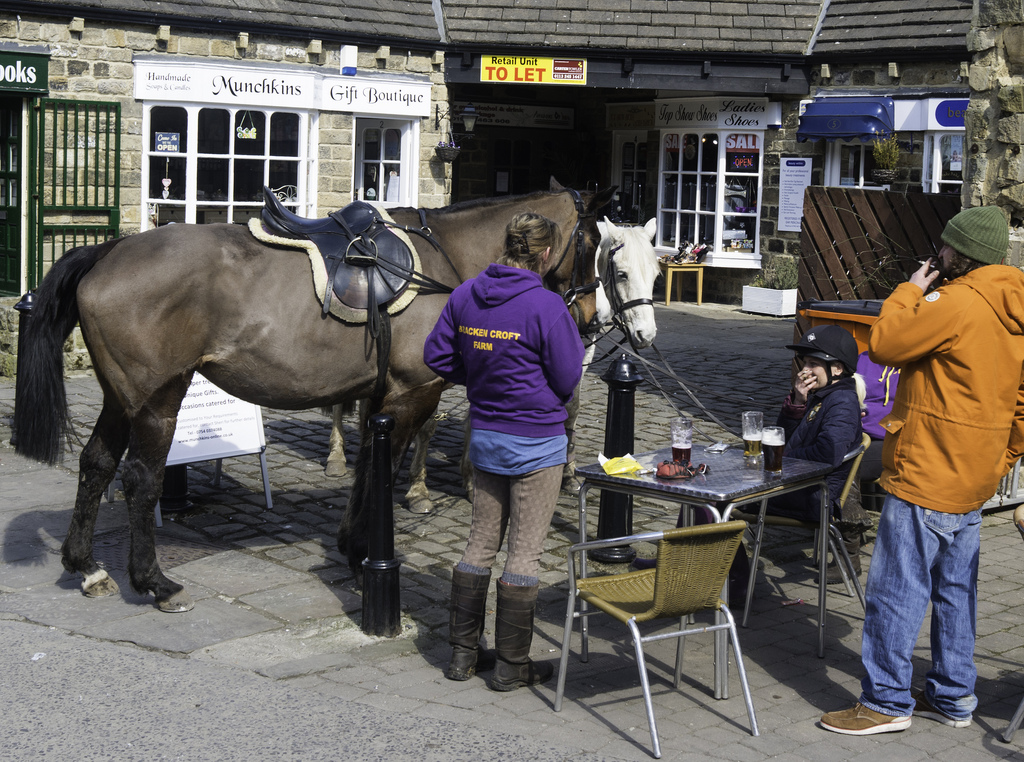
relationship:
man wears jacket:
[843, 192, 1018, 750] [855, 267, 1022, 520]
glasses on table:
[664, 404, 764, 463] [564, 426, 845, 504]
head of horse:
[584, 217, 695, 388] [562, 174, 716, 376]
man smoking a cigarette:
[820, 205, 1024, 736] [915, 245, 939, 269]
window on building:
[165, 119, 315, 219] [76, 18, 481, 291]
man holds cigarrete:
[820, 205, 1024, 736] [907, 252, 933, 274]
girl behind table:
[632, 324, 867, 605] [549, 427, 846, 624]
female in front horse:
[408, 181, 601, 698] [9, 173, 601, 619]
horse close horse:
[320, 215, 664, 514] [9, 173, 601, 619]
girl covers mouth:
[632, 324, 867, 605] [795, 371, 817, 385]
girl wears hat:
[632, 324, 867, 605] [780, 315, 858, 367]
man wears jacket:
[820, 205, 1024, 736] [868, 264, 1023, 514]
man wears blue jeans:
[820, 205, 1024, 736] [855, 497, 992, 709]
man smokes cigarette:
[843, 192, 1018, 750] [903, 248, 936, 277]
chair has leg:
[555, 512, 759, 759] [717, 594, 761, 739]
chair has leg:
[555, 512, 759, 759] [624, 615, 670, 760]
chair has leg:
[555, 512, 759, 759] [548, 574, 572, 717]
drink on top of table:
[758, 419, 785, 480] [568, 438, 843, 668]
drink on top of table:
[667, 417, 693, 472] [568, 438, 843, 668]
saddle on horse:
[248, 175, 419, 329] [9, 173, 601, 619]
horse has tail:
[9, 173, 601, 619] [14, 238, 108, 463]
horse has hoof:
[9, 173, 601, 619] [153, 585, 199, 618]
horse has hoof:
[9, 173, 601, 619] [79, 568, 121, 601]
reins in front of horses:
[619, 332, 736, 445] [1, 181, 665, 620]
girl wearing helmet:
[727, 315, 866, 614] [782, 322, 862, 375]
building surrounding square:
[0, 0, 1023, 387] [4, 302, 1022, 760]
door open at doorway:
[0, 90, 37, 298] [28, 99, 121, 292]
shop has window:
[438, 0, 1020, 305] [650, 129, 759, 270]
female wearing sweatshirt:
[423, 205, 586, 691] [419, 250, 584, 436]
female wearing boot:
[423, 205, 586, 691] [442, 557, 497, 685]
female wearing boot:
[423, 205, 586, 691] [488, 574, 558, 689]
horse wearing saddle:
[9, 173, 601, 619] [246, 186, 424, 325]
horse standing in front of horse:
[326, 212, 666, 519] [9, 173, 601, 619]